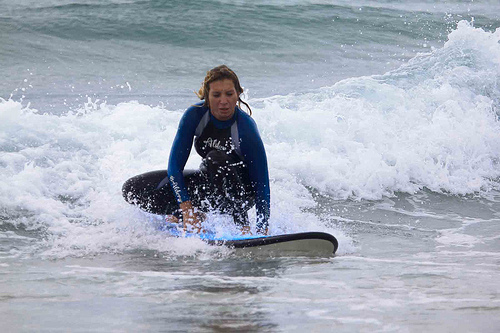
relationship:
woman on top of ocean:
[121, 63, 271, 237] [1, 1, 499, 333]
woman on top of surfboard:
[121, 63, 271, 237] [159, 224, 337, 258]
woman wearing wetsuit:
[121, 63, 271, 237] [121, 101, 270, 225]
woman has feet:
[121, 63, 271, 237] [162, 216, 254, 236]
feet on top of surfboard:
[162, 216, 254, 236] [159, 224, 337, 258]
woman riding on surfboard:
[121, 63, 271, 237] [159, 224, 337, 258]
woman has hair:
[121, 63, 271, 237] [193, 63, 253, 114]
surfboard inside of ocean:
[159, 224, 337, 258] [1, 1, 499, 333]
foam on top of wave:
[1, 94, 499, 254] [1, 17, 499, 222]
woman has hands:
[121, 63, 271, 237] [180, 204, 269, 238]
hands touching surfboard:
[180, 204, 269, 238] [159, 224, 337, 258]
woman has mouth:
[121, 63, 271, 237] [218, 107, 231, 112]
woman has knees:
[121, 63, 271, 237] [122, 148, 227, 198]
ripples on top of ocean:
[0, 2, 499, 72] [1, 1, 499, 333]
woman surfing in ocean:
[121, 63, 271, 237] [1, 1, 499, 333]